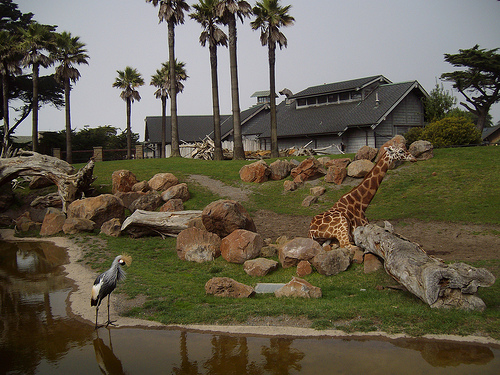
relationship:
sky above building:
[0, 3, 500, 143] [134, 72, 422, 152]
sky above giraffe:
[0, 3, 500, 143] [296, 147, 420, 253]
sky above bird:
[0, 3, 500, 143] [84, 246, 140, 334]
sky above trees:
[0, 3, 500, 143] [6, 1, 291, 164]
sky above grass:
[0, 3, 500, 143] [84, 162, 492, 318]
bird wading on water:
[74, 245, 134, 326] [69, 300, 299, 370]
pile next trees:
[184, 130, 225, 162] [6, 1, 291, 164]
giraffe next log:
[310, 124, 430, 236] [350, 208, 497, 320]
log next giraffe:
[355, 210, 493, 311] [304, 121, 440, 255]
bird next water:
[92, 255, 134, 327] [1, 245, 498, 374]